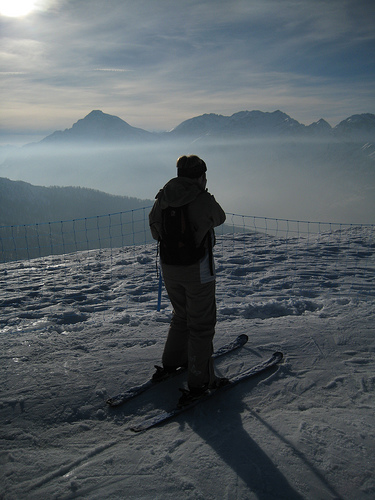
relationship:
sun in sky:
[3, 4, 60, 66] [3, 1, 373, 129]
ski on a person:
[133, 347, 283, 431] [147, 155, 226, 394]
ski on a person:
[108, 333, 283, 434] [147, 155, 226, 394]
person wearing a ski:
[147, 155, 226, 394] [133, 347, 283, 431]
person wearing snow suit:
[147, 155, 226, 394] [147, 181, 226, 387]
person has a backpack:
[147, 155, 226, 394] [157, 189, 217, 275]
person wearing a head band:
[147, 155, 226, 394] [175, 162, 205, 176]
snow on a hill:
[2, 227, 372, 499] [3, 176, 373, 498]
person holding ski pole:
[147, 155, 226, 394] [158, 269, 163, 312]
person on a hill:
[147, 155, 226, 394] [3, 176, 373, 498]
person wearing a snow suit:
[147, 155, 226, 394] [147, 181, 226, 387]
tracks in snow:
[84, 306, 126, 316] [2, 227, 372, 499]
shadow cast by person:
[153, 373, 297, 496] [147, 155, 226, 394]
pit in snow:
[236, 303, 294, 319] [2, 227, 372, 499]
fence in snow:
[1, 214, 374, 273] [2, 227, 372, 499]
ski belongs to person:
[133, 347, 283, 431] [147, 155, 226, 394]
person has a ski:
[147, 155, 226, 394] [108, 333, 283, 434]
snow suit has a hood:
[147, 181, 226, 387] [158, 179, 201, 206]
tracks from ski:
[84, 306, 126, 316] [133, 347, 283, 431]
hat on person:
[175, 153, 208, 180] [147, 155, 226, 394]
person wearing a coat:
[147, 155, 226, 394] [148, 178, 226, 251]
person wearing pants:
[147, 155, 226, 394] [160, 256, 220, 377]